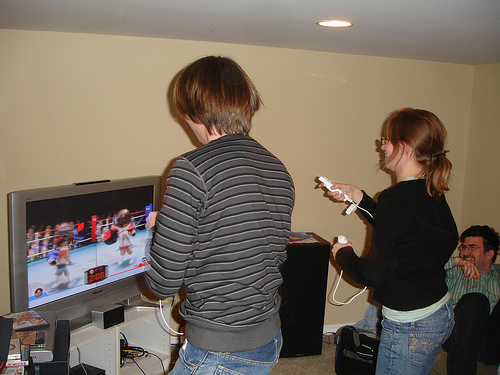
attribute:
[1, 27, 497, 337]
wall — beige, tall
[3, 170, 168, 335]
tv — silver, flat screen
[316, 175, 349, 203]
controller — white 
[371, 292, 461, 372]
jeans — blue 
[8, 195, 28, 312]
frame — grey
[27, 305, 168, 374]
tv stand — white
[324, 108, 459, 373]
girl — wearing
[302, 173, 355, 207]
controller — wii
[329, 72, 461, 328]
woman' — holding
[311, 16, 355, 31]
light — white 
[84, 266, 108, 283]
timer — red, digital, displayed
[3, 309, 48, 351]
games — piled up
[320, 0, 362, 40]
game — video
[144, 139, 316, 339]
shirt — grey 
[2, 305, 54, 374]
dvds — random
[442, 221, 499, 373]
man — sitting down, laughing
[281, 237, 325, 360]
speakers — black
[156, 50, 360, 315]
man — playing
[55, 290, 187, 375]
tv stand — white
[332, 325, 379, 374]
bag — black 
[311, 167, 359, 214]
controller — wii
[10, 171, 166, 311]
game — boxing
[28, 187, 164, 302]
game — video